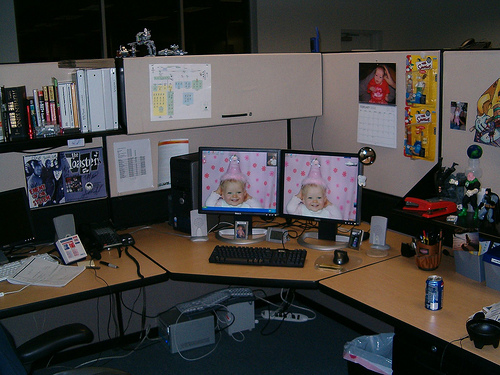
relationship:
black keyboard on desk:
[203, 237, 310, 277] [2, 208, 498, 367]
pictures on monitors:
[202, 151, 352, 218] [198, 145, 366, 227]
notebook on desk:
[6, 251, 86, 286] [2, 208, 498, 367]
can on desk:
[424, 273, 443, 311] [2, 208, 498, 367]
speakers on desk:
[187, 210, 387, 249] [2, 208, 498, 367]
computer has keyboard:
[197, 145, 364, 267] [204, 242, 307, 268]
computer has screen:
[197, 145, 364, 267] [280, 148, 360, 222]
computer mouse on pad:
[323, 240, 363, 274] [315, 250, 364, 273]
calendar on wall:
[356, 60, 401, 150] [288, 48, 498, 211]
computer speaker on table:
[364, 202, 401, 266] [2, 197, 499, 368]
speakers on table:
[187, 210, 387, 249] [1, 204, 485, 360]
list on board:
[112, 136, 154, 193] [103, 119, 288, 198]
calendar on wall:
[356, 60, 401, 150] [254, 4, 497, 71]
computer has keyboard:
[197, 145, 364, 267] [209, 240, 308, 268]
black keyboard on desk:
[203, 237, 310, 277] [15, 211, 485, 357]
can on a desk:
[424, 273, 443, 311] [2, 208, 498, 367]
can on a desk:
[424, 273, 443, 311] [257, 243, 444, 335]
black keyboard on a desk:
[203, 237, 310, 277] [103, 201, 385, 307]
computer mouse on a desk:
[323, 240, 363, 274] [2, 208, 498, 367]